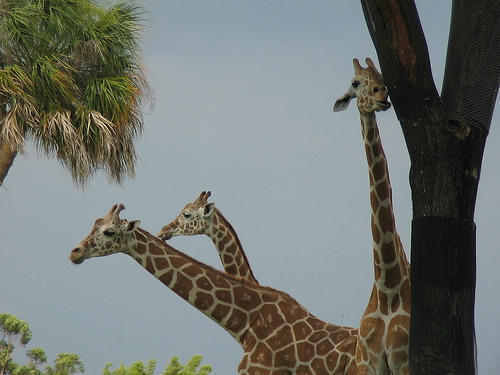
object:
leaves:
[50, 349, 84, 374]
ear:
[333, 87, 353, 116]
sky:
[0, 0, 500, 375]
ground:
[373, 104, 416, 151]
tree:
[361, 0, 499, 375]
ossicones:
[109, 204, 126, 216]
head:
[66, 203, 144, 266]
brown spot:
[389, 291, 402, 315]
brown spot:
[377, 205, 396, 233]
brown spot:
[372, 140, 382, 157]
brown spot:
[363, 283, 378, 315]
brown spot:
[393, 351, 409, 367]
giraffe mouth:
[70, 252, 85, 263]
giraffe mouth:
[156, 230, 170, 240]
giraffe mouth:
[373, 97, 393, 109]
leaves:
[162, 353, 213, 373]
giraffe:
[331, 57, 410, 374]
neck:
[359, 113, 401, 267]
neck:
[210, 225, 256, 284]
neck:
[137, 226, 252, 341]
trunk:
[359, 0, 500, 375]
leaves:
[0, 0, 148, 188]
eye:
[351, 81, 360, 89]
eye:
[184, 212, 191, 219]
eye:
[102, 226, 119, 237]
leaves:
[1, 307, 57, 374]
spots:
[148, 250, 181, 283]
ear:
[198, 202, 216, 219]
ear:
[125, 219, 143, 230]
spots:
[272, 325, 293, 350]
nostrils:
[74, 247, 79, 252]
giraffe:
[155, 190, 260, 374]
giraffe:
[69, 202, 357, 375]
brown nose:
[69, 248, 83, 255]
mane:
[136, 225, 287, 296]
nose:
[155, 226, 172, 241]